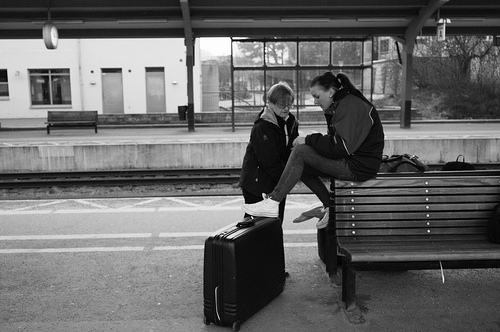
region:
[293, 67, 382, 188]
woman sitting on back of bench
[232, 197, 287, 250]
white shoe on luggage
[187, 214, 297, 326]
suitcase sitting on the ground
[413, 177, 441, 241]
bolts in wood bench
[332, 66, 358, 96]
pony tail on woman's head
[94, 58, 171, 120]
two doors on building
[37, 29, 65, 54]
clock hanging from roof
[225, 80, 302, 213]
standing person in coat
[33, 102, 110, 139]
empty bench on platform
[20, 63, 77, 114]
window on side of building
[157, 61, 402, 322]
an old woman and a young woman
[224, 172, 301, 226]
woman is wearing white sneakers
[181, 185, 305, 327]
suitcase with wheels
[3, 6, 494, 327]
open air train station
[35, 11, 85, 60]
analog clock hanging from the ceiling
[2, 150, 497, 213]
train tracks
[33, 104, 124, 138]
bench on the train platform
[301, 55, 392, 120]
woman has a ponytail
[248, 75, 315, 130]
old woman is wearing glasses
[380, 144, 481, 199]
bags sitting on the bench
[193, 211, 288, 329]
Hard shell suitcase sitting on pavement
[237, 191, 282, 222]
White tennis shoe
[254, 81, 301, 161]
Person wearing glasses looking down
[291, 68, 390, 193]
Girl sitting on top of bench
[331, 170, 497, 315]
Wooden slatted bench on pavement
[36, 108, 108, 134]
Bench on pavement across the tracks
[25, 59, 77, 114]
Window in building across the tracks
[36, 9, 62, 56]
Clock hanging from roof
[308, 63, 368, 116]
Girl with hair in ponytail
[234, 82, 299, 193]
Person looking down wearing a jacket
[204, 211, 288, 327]
large black suitcase with wheels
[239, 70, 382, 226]
woman sitting on top of bench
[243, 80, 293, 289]
man looking down at woman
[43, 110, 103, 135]
empty bench in the background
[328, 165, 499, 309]
wooden bench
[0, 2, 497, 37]
roof over wating area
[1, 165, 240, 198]
train tracks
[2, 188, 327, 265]
white markings on the sidewalk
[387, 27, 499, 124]
tree in the background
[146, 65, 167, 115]
door leading into building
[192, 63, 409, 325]
woman sitting on top of bench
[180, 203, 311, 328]
black suitcase with wheels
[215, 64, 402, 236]
woman wearing white snickers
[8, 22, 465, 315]
black and white picture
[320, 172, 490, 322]
wooden bench fastened to ground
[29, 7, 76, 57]
clock attached to ceiling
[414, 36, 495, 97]
trees with no leaves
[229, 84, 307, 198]
person wearing glasses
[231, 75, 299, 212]
person wearing dark jacket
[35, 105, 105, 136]
bench fastened to ground